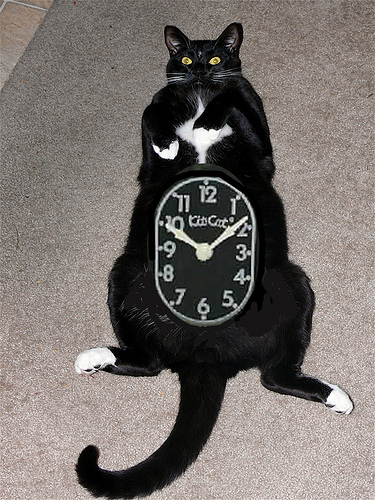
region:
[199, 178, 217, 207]
a number on a clock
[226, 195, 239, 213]
a number on a clock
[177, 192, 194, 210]
a number on a clock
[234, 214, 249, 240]
a number on a clock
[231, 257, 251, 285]
a number on a clock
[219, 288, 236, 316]
a number on a clock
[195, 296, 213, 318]
a number on a clock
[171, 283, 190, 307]
a number on a clock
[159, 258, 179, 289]
a number on a clock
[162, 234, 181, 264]
a number on a clock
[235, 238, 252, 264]
a number on a clock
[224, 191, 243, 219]
a number on a clock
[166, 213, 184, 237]
a number on a clock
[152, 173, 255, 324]
black and white oval clock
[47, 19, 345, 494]
black and white big cat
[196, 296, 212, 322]
white number 6 on clock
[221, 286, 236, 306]
white number 5 on clock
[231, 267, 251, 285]
white number 4 on clock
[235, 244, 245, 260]
white number 3 on clock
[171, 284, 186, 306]
white number 7 on clock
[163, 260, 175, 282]
white number 8 on clock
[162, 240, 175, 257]
white number 9 on clock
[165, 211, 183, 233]
white number 10 on clock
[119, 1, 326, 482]
a black cat clock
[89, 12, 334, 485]
a realistic cat clock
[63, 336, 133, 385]
a white cat paw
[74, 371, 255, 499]
a black cat's tail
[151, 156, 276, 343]
a black clock with white arms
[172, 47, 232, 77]
two yellow cat eyes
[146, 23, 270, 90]
a black cat's face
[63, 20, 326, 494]
a fake cat with clock on stomach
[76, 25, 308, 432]
a cat with a black clock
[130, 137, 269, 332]
a clock for telling time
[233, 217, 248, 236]
a number on a clock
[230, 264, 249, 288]
a number on a clock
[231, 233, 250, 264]
a number on a clock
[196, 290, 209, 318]
a number on a clock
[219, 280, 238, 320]
a number on a clock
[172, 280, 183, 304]
a number on a clock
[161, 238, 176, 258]
a number on a clock